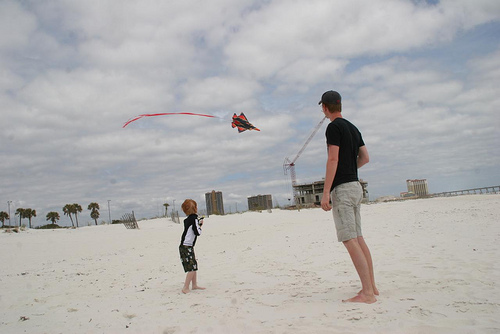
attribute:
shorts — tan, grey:
[330, 181, 365, 241]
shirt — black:
[326, 116, 365, 190]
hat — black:
[319, 90, 343, 107]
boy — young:
[179, 199, 206, 294]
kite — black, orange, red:
[123, 111, 261, 133]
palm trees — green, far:
[1, 201, 101, 230]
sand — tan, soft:
[1, 192, 499, 333]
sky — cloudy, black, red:
[0, 1, 500, 227]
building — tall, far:
[206, 190, 225, 216]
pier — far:
[383, 184, 500, 200]